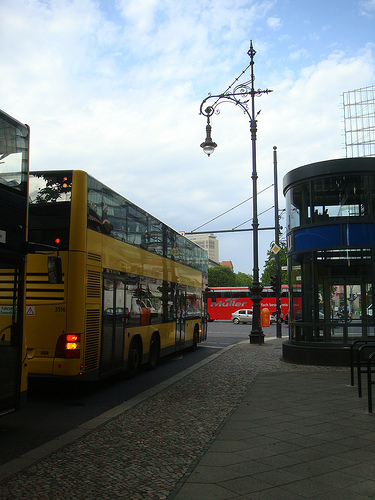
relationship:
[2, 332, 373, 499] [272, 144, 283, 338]
sidewalk under post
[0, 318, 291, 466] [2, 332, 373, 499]
road next to sidewalk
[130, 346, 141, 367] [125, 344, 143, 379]
rim of tire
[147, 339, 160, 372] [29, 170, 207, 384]
tire on bus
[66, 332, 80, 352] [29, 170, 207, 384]
tail light on bus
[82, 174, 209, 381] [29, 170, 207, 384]
side of bus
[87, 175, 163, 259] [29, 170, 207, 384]
window on bus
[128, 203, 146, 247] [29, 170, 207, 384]
window on bus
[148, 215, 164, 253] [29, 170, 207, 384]
window on bus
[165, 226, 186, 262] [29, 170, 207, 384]
window on bus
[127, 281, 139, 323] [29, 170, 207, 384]
window on bus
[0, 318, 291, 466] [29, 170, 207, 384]
road under bus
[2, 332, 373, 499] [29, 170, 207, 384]
sidewalk next to bus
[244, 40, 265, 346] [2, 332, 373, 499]
post on sidewalk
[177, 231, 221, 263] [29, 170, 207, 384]
building behind bus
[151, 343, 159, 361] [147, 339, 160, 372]
rim on tire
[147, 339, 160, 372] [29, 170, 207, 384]
tire under bus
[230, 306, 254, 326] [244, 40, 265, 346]
car behind post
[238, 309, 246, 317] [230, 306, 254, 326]
window on car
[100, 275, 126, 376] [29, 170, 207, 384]
door on bus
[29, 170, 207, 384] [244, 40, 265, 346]
bus next to post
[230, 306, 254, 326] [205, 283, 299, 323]
car next to bus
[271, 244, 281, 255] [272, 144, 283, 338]
diamond on post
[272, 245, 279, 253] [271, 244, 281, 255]
diamond on diamond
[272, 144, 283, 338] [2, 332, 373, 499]
post on sidewalk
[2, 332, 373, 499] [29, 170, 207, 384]
sidewalk near bus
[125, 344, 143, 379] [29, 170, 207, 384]
tire of bus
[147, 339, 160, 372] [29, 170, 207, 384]
tire of bus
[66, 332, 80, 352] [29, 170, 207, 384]
tail light of bus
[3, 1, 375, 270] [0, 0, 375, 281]
clouds cover sky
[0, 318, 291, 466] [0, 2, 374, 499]
road in city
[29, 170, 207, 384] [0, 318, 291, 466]
bus on road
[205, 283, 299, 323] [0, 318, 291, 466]
bus on road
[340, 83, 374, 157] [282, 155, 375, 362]
scaffolding behind building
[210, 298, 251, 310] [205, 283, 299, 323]
logo on bus